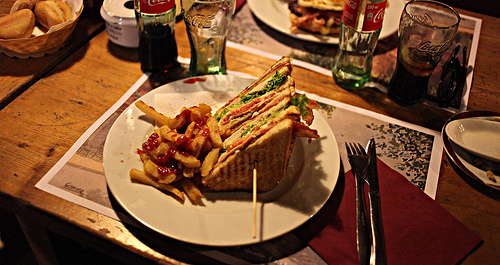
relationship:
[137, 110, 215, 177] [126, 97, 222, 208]
ketchup on fries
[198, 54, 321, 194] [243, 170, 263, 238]
sandwich on stick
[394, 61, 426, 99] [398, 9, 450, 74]
coke in glass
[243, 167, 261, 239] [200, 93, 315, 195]
stick in sandwich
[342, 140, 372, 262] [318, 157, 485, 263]
fork on napkin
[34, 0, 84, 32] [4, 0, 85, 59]
roll in basket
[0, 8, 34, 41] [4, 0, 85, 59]
roll in basket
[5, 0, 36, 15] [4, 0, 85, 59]
roll in basket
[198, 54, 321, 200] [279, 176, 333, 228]
sandwich on plate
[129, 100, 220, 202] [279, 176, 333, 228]
fries on plate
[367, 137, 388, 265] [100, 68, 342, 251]
knife on table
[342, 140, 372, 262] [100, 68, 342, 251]
fork on table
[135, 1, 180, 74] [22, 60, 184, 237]
bottle on table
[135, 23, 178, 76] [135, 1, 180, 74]
coke in bottle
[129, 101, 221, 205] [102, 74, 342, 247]
fries on plate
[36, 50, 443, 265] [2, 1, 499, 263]
mat on table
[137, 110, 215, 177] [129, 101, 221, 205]
ketchup on fries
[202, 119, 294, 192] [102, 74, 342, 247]
bread on plate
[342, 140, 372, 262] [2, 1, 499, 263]
fork on table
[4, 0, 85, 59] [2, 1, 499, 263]
basket sitting on table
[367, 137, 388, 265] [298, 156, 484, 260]
knife on napkin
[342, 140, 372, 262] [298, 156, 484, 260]
fork on napkin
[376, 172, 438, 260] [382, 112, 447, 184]
napkin on paper placemat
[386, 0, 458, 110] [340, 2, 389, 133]
cup next to soda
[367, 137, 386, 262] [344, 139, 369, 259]
knife and fork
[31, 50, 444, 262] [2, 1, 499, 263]
mat on table